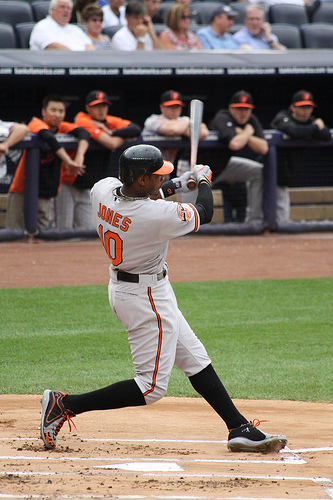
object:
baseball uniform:
[89, 176, 211, 406]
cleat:
[227, 419, 288, 454]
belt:
[109, 264, 167, 284]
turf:
[168, 277, 322, 399]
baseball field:
[0, 232, 333, 500]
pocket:
[114, 288, 138, 299]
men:
[0, 87, 332, 223]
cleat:
[41, 388, 76, 450]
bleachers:
[0, 1, 333, 239]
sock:
[188, 363, 249, 431]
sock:
[62, 378, 145, 415]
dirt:
[134, 419, 180, 435]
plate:
[92, 451, 192, 490]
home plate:
[91, 458, 183, 476]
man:
[39, 144, 287, 454]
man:
[246, 89, 333, 226]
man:
[231, 0, 289, 52]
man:
[55, 92, 142, 232]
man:
[139, 88, 209, 184]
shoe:
[226, 418, 287, 453]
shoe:
[40, 388, 78, 448]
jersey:
[90, 176, 201, 277]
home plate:
[98, 456, 193, 484]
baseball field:
[0, 238, 331, 499]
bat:
[186, 99, 203, 192]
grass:
[219, 286, 314, 351]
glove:
[193, 165, 212, 185]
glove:
[172, 169, 197, 195]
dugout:
[1, 47, 331, 230]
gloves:
[171, 164, 213, 194]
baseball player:
[41, 99, 289, 454]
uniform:
[90, 176, 210, 406]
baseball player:
[0, 90, 329, 229]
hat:
[289, 90, 315, 111]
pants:
[108, 266, 212, 407]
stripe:
[143, 282, 163, 397]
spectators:
[29, 0, 287, 55]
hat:
[118, 144, 174, 182]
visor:
[151, 160, 174, 175]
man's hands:
[174, 165, 215, 193]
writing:
[97, 203, 132, 267]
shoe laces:
[55, 411, 78, 436]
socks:
[64, 363, 249, 431]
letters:
[97, 202, 132, 231]